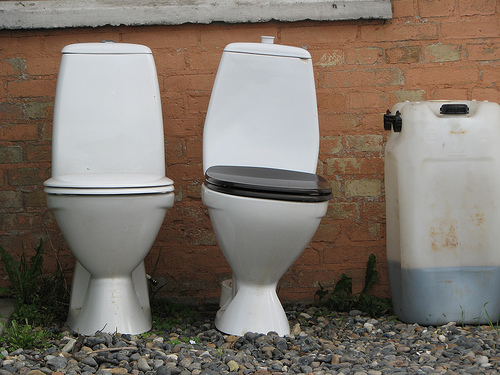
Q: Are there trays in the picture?
A: No, there are no trays.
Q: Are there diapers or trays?
A: No, there are no trays or diapers.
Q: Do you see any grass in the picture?
A: Yes, there is grass.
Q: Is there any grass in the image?
A: Yes, there is grass.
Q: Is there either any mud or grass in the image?
A: Yes, there is grass.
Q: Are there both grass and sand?
A: No, there is grass but no sand.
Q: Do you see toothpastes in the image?
A: No, there are no toothpastes.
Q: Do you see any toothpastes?
A: No, there are no toothpastes.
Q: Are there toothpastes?
A: No, there are no toothpastes.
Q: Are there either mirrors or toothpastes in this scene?
A: No, there are no toothpastes or mirrors.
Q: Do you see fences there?
A: No, there are no fences.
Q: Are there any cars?
A: No, there are no cars.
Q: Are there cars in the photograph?
A: No, there are no cars.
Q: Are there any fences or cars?
A: No, there are no cars or fences.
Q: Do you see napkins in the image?
A: No, there are no napkins.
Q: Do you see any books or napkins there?
A: No, there are no napkins or books.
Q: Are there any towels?
A: No, there are no towels.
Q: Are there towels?
A: No, there are no towels.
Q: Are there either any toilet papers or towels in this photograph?
A: No, there are no towels or toilet papers.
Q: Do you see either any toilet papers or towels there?
A: No, there are no towels or toilet papers.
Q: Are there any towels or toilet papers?
A: No, there are no towels or toilet papers.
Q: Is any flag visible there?
A: No, there are no flags.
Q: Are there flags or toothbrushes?
A: No, there are no flags or toothbrushes.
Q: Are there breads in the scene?
A: No, there are no breads.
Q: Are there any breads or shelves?
A: No, there are no breads or shelves.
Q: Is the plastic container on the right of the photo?
A: Yes, the container is on the right of the image.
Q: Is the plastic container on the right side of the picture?
A: Yes, the container is on the right of the image.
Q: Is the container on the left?
A: No, the container is on the right of the image.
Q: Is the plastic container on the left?
A: No, the container is on the right of the image.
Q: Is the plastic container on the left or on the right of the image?
A: The container is on the right of the image.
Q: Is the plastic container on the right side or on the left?
A: The container is on the right of the image.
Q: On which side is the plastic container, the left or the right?
A: The container is on the right of the image.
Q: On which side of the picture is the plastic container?
A: The container is on the right of the image.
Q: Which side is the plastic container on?
A: The container is on the right of the image.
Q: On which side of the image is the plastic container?
A: The container is on the right of the image.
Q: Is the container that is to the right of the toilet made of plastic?
A: Yes, the container is made of plastic.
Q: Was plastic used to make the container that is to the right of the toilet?
A: Yes, the container is made of plastic.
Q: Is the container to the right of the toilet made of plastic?
A: Yes, the container is made of plastic.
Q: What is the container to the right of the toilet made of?
A: The container is made of plastic.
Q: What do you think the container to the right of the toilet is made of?
A: The container is made of plastic.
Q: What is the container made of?
A: The container is made of plastic.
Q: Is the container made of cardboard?
A: No, the container is made of plastic.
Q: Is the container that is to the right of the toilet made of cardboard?
A: No, the container is made of plastic.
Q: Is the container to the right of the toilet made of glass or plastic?
A: The container is made of plastic.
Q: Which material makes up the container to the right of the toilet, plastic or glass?
A: The container is made of plastic.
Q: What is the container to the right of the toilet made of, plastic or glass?
A: The container is made of plastic.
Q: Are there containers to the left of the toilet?
A: No, the container is to the right of the toilet.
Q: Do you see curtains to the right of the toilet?
A: No, there is a container to the right of the toilet.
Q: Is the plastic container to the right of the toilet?
A: Yes, the container is to the right of the toilet.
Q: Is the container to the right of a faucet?
A: No, the container is to the right of the toilet.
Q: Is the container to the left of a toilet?
A: No, the container is to the right of a toilet.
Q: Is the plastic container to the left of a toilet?
A: No, the container is to the right of a toilet.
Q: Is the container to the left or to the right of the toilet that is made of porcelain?
A: The container is to the right of the toilet.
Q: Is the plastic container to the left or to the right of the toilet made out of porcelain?
A: The container is to the right of the toilet.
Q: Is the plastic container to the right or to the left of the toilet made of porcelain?
A: The container is to the right of the toilet.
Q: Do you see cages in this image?
A: No, there are no cages.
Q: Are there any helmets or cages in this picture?
A: No, there are no cages or helmets.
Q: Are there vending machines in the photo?
A: No, there are no vending machines.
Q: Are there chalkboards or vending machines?
A: No, there are no vending machines or chalkboards.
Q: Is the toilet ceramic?
A: Yes, the toilet is ceramic.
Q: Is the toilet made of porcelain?
A: Yes, the toilet is made of porcelain.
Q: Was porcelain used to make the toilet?
A: Yes, the toilet is made of porcelain.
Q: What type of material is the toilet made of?
A: The toilet is made of porcelain.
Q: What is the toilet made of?
A: The toilet is made of porcelain.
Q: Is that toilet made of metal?
A: No, the toilet is made of porcelain.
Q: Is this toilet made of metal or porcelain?
A: The toilet is made of porcelain.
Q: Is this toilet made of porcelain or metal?
A: The toilet is made of porcelain.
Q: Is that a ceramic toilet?
A: Yes, that is a ceramic toilet.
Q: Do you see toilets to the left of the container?
A: Yes, there is a toilet to the left of the container.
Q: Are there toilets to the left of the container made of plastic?
A: Yes, there is a toilet to the left of the container.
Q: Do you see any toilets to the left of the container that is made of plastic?
A: Yes, there is a toilet to the left of the container.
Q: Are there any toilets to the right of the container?
A: No, the toilet is to the left of the container.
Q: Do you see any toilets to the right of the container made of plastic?
A: No, the toilet is to the left of the container.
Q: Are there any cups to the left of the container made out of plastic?
A: No, there is a toilet to the left of the container.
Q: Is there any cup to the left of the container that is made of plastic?
A: No, there is a toilet to the left of the container.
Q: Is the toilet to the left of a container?
A: Yes, the toilet is to the left of a container.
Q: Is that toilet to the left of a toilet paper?
A: No, the toilet is to the left of a container.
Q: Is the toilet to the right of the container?
A: No, the toilet is to the left of the container.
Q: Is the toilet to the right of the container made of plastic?
A: No, the toilet is to the left of the container.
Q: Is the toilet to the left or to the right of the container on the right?
A: The toilet is to the left of the container.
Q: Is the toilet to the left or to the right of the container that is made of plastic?
A: The toilet is to the left of the container.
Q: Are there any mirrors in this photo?
A: No, there are no mirrors.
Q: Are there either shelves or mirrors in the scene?
A: No, there are no mirrors or shelves.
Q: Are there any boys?
A: No, there are no boys.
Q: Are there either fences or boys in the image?
A: No, there are no boys or fences.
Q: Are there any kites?
A: No, there are no kites.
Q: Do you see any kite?
A: No, there are no kites.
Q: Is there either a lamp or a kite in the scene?
A: No, there are no kites or lamps.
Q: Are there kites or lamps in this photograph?
A: No, there are no kites or lamps.